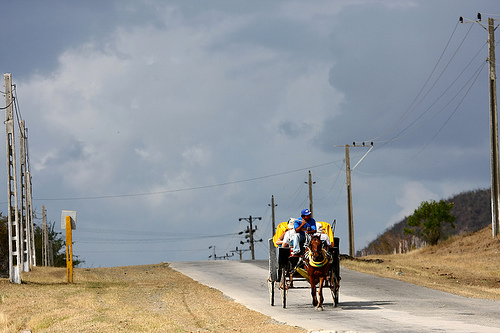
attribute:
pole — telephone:
[459, 15, 499, 239]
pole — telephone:
[349, 141, 352, 260]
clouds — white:
[110, 68, 175, 128]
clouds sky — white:
[174, 193, 235, 233]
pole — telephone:
[339, 141, 383, 259]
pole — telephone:
[488, 16, 498, 237]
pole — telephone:
[301, 167, 317, 219]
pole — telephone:
[264, 189, 281, 258]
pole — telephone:
[236, 212, 263, 262]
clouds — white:
[50, 9, 400, 201]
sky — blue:
[3, 6, 490, 223]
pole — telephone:
[483, 15, 498, 235]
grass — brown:
[109, 279, 130, 304]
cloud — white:
[420, 54, 462, 104]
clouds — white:
[115, 97, 191, 147]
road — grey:
[166, 257, 499, 331]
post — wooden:
[343, 145, 356, 261]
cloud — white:
[113, 4, 139, 18]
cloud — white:
[11, 27, 330, 159]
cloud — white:
[144, 175, 219, 211]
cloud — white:
[67, 162, 121, 194]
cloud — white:
[31, 149, 57, 176]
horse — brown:
[289, 228, 342, 303]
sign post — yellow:
[61, 212, 75, 279]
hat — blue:
[301, 207, 311, 217]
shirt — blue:
[292, 216, 316, 236]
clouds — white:
[38, 7, 452, 225]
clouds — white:
[2, 3, 493, 263]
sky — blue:
[0, 2, 498, 270]